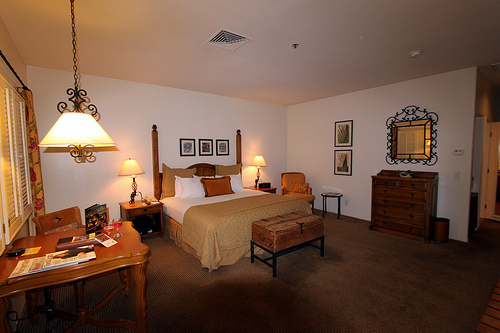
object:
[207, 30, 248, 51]
vent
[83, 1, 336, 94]
ceiling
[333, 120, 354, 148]
picture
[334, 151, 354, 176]
picture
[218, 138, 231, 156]
picture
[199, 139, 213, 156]
picture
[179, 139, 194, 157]
picture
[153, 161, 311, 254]
bed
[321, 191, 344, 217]
table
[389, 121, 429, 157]
mirror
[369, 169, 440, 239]
dresser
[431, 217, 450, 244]
can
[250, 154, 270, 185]
lamp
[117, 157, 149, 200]
lamp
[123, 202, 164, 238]
stand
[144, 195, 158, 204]
phone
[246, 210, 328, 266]
chest